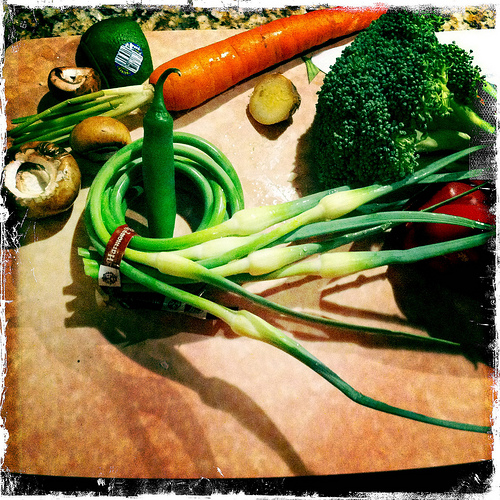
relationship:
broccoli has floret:
[306, 4, 494, 190] [392, 68, 495, 141]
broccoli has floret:
[306, 4, 494, 190] [434, 37, 500, 108]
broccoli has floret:
[306, 4, 494, 190] [347, 119, 472, 178]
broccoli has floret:
[306, 4, 494, 190] [310, 156, 470, 192]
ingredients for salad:
[8, 4, 493, 453] [8, 8, 494, 440]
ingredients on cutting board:
[8, 4, 493, 453] [7, 29, 491, 477]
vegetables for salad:
[3, 8, 496, 435] [8, 8, 494, 440]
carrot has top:
[8, 6, 392, 152] [7, 73, 158, 160]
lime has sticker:
[76, 12, 155, 89] [110, 39, 146, 80]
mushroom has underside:
[4, 139, 83, 225] [1, 153, 61, 201]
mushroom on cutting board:
[4, 139, 83, 225] [7, 29, 491, 477]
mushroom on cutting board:
[70, 113, 133, 167] [7, 29, 491, 477]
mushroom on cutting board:
[45, 63, 105, 105] [7, 29, 491, 477]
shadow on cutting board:
[4, 32, 495, 479] [7, 29, 491, 477]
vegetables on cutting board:
[3, 8, 496, 435] [7, 29, 491, 477]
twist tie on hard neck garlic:
[93, 224, 243, 332] [62, 126, 494, 446]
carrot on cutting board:
[8, 6, 392, 152] [7, 29, 491, 477]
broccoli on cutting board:
[306, 4, 494, 190] [7, 29, 491, 477]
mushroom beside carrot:
[70, 113, 133, 167] [8, 6, 392, 152]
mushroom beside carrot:
[45, 63, 105, 105] [8, 6, 392, 152]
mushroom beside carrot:
[4, 139, 83, 225] [8, 6, 392, 152]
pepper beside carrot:
[135, 63, 185, 239] [8, 6, 392, 152]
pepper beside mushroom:
[135, 63, 185, 239] [4, 139, 83, 225]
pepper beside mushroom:
[135, 63, 185, 239] [70, 113, 133, 167]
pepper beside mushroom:
[135, 63, 185, 239] [45, 63, 105, 105]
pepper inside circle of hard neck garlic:
[135, 63, 185, 239] [62, 126, 494, 446]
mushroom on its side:
[70, 113, 133, 167] [80, 151, 117, 164]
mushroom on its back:
[4, 139, 83, 225] [16, 204, 73, 228]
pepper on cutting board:
[392, 168, 500, 272] [7, 29, 491, 477]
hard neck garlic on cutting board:
[62, 126, 494, 446] [7, 29, 491, 477]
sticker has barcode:
[110, 39, 146, 80] [117, 46, 142, 72]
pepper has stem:
[140, 67, 180, 239] [146, 66, 187, 113]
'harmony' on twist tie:
[104, 227, 133, 267] [93, 224, 243, 332]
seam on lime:
[78, 37, 112, 90] [76, 12, 155, 89]